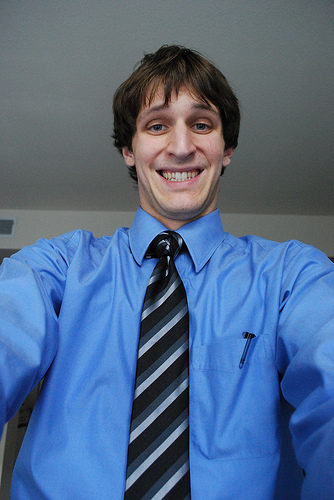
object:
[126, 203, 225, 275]
collar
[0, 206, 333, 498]
blue shirt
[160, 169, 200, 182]
teeth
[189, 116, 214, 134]
eye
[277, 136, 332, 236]
wall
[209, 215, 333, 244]
wall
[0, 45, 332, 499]
man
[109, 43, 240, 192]
hair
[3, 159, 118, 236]
wall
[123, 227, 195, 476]
necktie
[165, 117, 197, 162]
nose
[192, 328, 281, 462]
pocket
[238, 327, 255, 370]
pen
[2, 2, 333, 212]
ceiling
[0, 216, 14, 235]
air vent